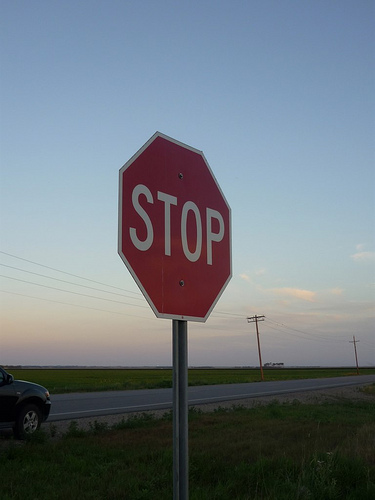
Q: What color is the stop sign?
A: Red.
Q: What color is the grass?
A: Green.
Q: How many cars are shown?
A: 1.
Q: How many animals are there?
A: 0.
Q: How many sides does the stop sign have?
A: 8.